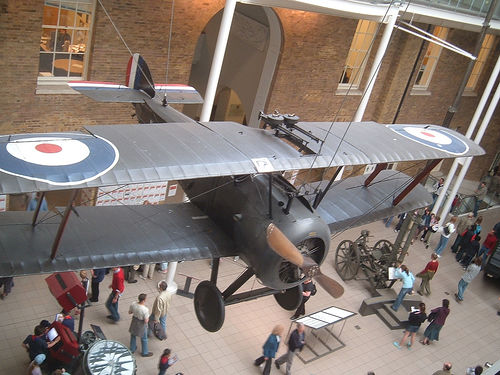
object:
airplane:
[8, 53, 490, 332]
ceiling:
[272, 5, 386, 30]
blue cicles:
[0, 133, 118, 183]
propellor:
[266, 223, 344, 299]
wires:
[99, 0, 163, 103]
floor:
[0, 216, 500, 375]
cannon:
[335, 229, 401, 284]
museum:
[4, 6, 498, 375]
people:
[149, 282, 176, 341]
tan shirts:
[128, 302, 149, 320]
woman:
[394, 264, 414, 312]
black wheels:
[193, 279, 226, 332]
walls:
[7, 7, 32, 55]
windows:
[39, 0, 94, 82]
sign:
[296, 307, 354, 330]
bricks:
[13, 76, 25, 81]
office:
[51, 38, 81, 73]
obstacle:
[336, 227, 425, 332]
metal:
[367, 259, 379, 275]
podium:
[359, 287, 425, 330]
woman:
[394, 302, 427, 350]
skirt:
[406, 325, 420, 333]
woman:
[253, 324, 286, 374]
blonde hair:
[273, 324, 285, 335]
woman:
[453, 256, 484, 305]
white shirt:
[440, 222, 457, 237]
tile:
[199, 343, 212, 359]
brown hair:
[400, 265, 409, 276]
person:
[105, 268, 124, 320]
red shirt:
[110, 267, 126, 293]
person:
[51, 26, 71, 52]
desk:
[40, 43, 53, 52]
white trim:
[35, 75, 81, 95]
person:
[290, 276, 315, 319]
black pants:
[296, 295, 311, 316]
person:
[278, 323, 303, 374]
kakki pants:
[278, 350, 299, 373]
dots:
[36, 143, 62, 153]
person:
[457, 259, 486, 302]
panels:
[87, 340, 136, 375]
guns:
[257, 111, 310, 153]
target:
[385, 122, 467, 155]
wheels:
[272, 278, 306, 312]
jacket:
[128, 316, 147, 337]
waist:
[133, 315, 143, 321]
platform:
[367, 295, 423, 304]